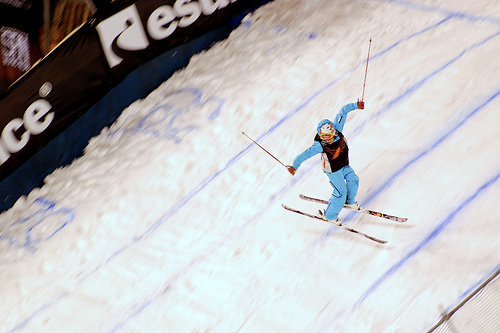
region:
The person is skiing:
[242, 35, 418, 276]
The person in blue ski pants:
[230, 30, 430, 245]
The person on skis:
[276, 185, 411, 250]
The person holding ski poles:
[242, 30, 417, 250]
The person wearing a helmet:
[231, 30, 421, 250]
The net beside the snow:
[425, 260, 495, 325]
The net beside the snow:
[5, 1, 115, 91]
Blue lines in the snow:
[201, 15, 481, 320]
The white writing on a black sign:
[6, 10, 246, 156]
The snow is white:
[93, 168, 358, 323]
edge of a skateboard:
[352, 225, 384, 255]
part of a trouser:
[320, 186, 348, 220]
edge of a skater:
[363, 207, 385, 228]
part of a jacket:
[319, 142, 346, 176]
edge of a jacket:
[313, 157, 338, 174]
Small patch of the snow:
[144, 195, 166, 208]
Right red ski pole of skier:
[240, 132, 293, 171]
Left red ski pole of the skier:
[353, 35, 370, 97]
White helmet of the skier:
[318, 122, 333, 138]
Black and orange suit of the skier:
[323, 145, 352, 167]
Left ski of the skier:
[353, 209, 408, 224]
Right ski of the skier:
[345, 226, 385, 252]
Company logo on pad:
[89, 4, 160, 87]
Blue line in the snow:
[169, 191, 220, 217]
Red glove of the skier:
[356, 101, 366, 111]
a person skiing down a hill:
[228, 39, 452, 266]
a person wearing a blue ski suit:
[301, 81, 391, 241]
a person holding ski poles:
[246, 25, 395, 201]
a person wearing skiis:
[260, 85, 425, 269]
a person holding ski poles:
[196, 30, 448, 267]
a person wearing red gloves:
[257, 75, 380, 203]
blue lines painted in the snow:
[169, 22, 468, 267]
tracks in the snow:
[92, 187, 253, 325]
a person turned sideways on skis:
[228, 40, 421, 254]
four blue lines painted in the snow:
[420, 17, 494, 227]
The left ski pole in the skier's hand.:
[238, 123, 302, 177]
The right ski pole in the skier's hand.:
[356, 34, 372, 110]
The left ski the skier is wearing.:
[281, 203, 387, 258]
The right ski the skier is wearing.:
[300, 181, 417, 232]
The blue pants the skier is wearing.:
[323, 172, 366, 213]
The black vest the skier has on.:
[313, 140, 355, 168]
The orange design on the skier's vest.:
[323, 142, 345, 159]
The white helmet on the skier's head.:
[311, 119, 341, 139]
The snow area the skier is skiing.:
[133, 85, 490, 331]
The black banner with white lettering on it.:
[2, 1, 242, 153]